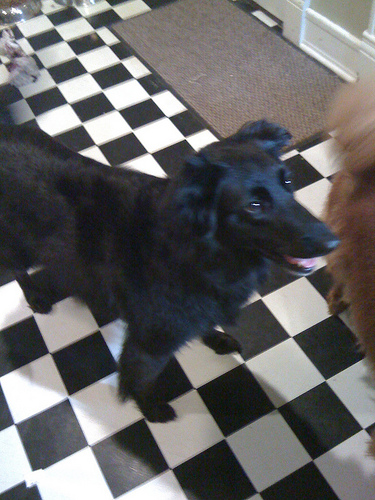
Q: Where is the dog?
A: Standing on the floor.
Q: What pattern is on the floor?
A: Black and white squares.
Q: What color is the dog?
A: Black.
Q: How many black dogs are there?
A: One.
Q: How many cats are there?
A: None.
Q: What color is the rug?
A: Brown.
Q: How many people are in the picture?
A: None.